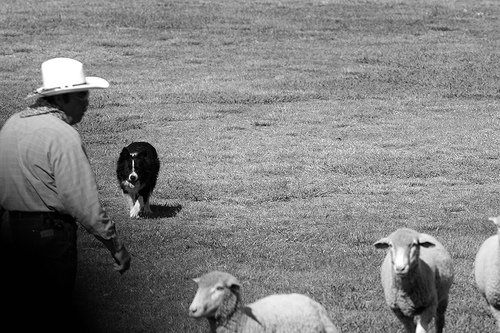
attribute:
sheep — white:
[461, 202, 498, 317]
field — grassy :
[4, 0, 497, 321]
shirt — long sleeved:
[1, 101, 123, 245]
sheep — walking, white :
[371, 227, 453, 331]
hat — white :
[22, 50, 136, 100]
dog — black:
[113, 141, 155, 216]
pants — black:
[13, 192, 129, 329]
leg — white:
[127, 192, 138, 215]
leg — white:
[130, 196, 142, 222]